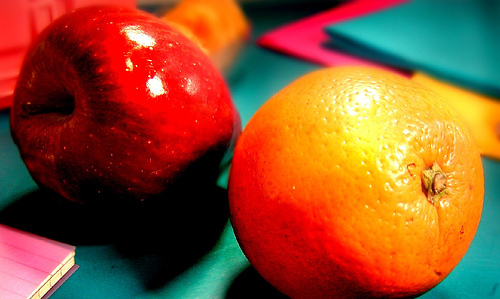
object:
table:
[1, 1, 498, 297]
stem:
[423, 165, 448, 197]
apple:
[9, 2, 241, 204]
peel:
[276, 112, 345, 167]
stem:
[19, 95, 75, 118]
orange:
[222, 43, 487, 295]